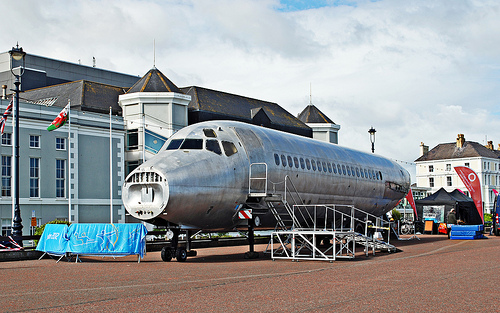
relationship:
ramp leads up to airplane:
[253, 225, 395, 261] [120, 120, 410, 262]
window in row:
[271, 152, 280, 166] [273, 148, 386, 181]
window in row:
[280, 154, 289, 166] [273, 148, 386, 181]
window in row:
[286, 154, 295, 170] [273, 148, 386, 181]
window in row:
[292, 155, 300, 168] [273, 148, 386, 181]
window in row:
[301, 157, 305, 171] [273, 148, 386, 181]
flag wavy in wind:
[45, 99, 72, 132] [43, 95, 77, 141]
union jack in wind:
[0, 95, 17, 138] [1, 88, 33, 154]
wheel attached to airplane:
[174, 243, 190, 261] [120, 120, 410, 262]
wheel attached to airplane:
[160, 241, 177, 261] [120, 120, 410, 262]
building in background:
[417, 137, 499, 214] [379, 113, 498, 228]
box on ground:
[450, 222, 483, 229] [4, 231, 496, 313]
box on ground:
[449, 230, 481, 237] [4, 231, 496, 313]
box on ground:
[447, 234, 481, 241] [4, 231, 496, 313]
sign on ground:
[35, 221, 144, 257] [4, 231, 496, 313]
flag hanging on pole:
[45, 99, 72, 132] [108, 105, 113, 225]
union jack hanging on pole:
[0, 95, 17, 138] [13, 73, 24, 244]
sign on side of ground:
[453, 164, 483, 227] [4, 231, 496, 313]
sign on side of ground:
[398, 191, 421, 220] [4, 231, 496, 313]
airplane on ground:
[120, 120, 410, 262] [4, 231, 496, 313]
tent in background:
[416, 189, 480, 230] [379, 113, 498, 228]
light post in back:
[368, 126, 375, 150] [379, 113, 498, 228]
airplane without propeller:
[120, 120, 410, 262] [122, 168, 167, 221]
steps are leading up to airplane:
[246, 186, 301, 233] [120, 120, 410, 262]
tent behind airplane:
[416, 189, 480, 230] [120, 120, 410, 262]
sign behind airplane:
[453, 164, 483, 227] [120, 120, 410, 262]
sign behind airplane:
[398, 191, 421, 220] [120, 120, 410, 262]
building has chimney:
[417, 137, 499, 214] [485, 141, 495, 152]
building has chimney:
[417, 137, 499, 214] [455, 131, 467, 154]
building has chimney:
[417, 137, 499, 214] [419, 140, 428, 158]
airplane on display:
[120, 120, 410, 262] [8, 129, 499, 311]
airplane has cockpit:
[120, 120, 410, 262] [168, 136, 241, 163]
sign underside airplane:
[237, 205, 255, 221] [120, 120, 410, 262]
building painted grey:
[2, 48, 339, 248] [3, 41, 341, 256]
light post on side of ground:
[368, 126, 375, 150] [4, 231, 496, 313]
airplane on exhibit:
[120, 120, 410, 262] [8, 129, 499, 311]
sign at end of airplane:
[398, 191, 421, 220] [120, 120, 410, 262]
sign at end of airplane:
[453, 164, 483, 227] [120, 120, 410, 262]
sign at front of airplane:
[35, 221, 144, 257] [120, 120, 410, 262]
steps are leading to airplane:
[246, 186, 301, 233] [120, 120, 410, 262]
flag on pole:
[45, 99, 72, 132] [66, 98, 72, 226]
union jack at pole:
[0, 95, 17, 138] [13, 73, 24, 244]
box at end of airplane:
[450, 222, 483, 229] [120, 120, 410, 262]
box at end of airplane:
[449, 230, 481, 237] [120, 120, 410, 262]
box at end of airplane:
[447, 234, 481, 241] [120, 120, 410, 262]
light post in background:
[368, 126, 375, 150] [379, 113, 498, 228]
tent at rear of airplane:
[416, 189, 480, 230] [120, 120, 410, 262]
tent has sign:
[416, 189, 480, 230] [423, 216, 435, 233]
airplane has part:
[120, 120, 410, 262] [172, 177, 225, 202]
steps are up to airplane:
[246, 186, 301, 233] [120, 120, 410, 262]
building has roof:
[417, 137, 499, 214] [413, 141, 499, 159]